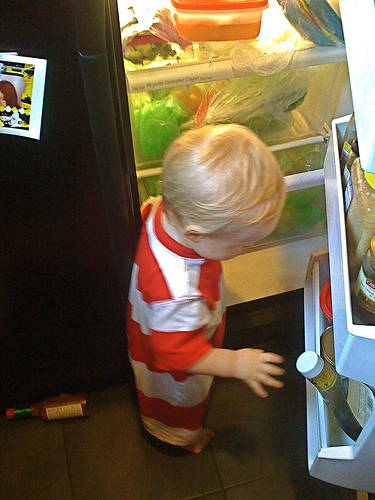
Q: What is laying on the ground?
A: Tabasco sauce.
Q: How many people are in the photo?
A: One.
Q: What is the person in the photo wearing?
A: A shirt.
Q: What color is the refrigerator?
A: Black.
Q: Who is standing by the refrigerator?
A: The child.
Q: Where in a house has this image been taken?
A: The kitchen.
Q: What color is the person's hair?
A: Blonde.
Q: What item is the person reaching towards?
A: Salad dressing.